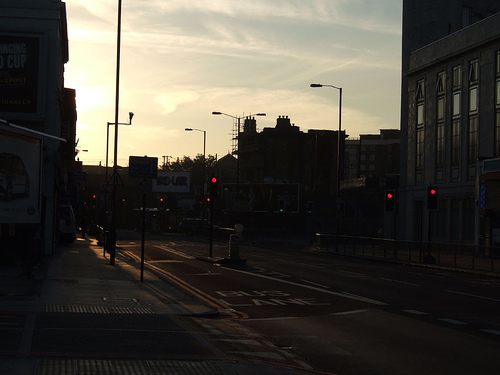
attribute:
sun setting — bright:
[68, 53, 109, 120]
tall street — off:
[100, 105, 407, 345]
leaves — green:
[176, 133, 221, 191]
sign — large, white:
[155, 168, 193, 195]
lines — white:
[139, 242, 499, 340]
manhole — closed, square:
[81, 279, 169, 317]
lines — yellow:
[131, 224, 269, 340]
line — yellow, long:
[162, 267, 217, 308]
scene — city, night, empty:
[6, 21, 417, 355]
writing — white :
[214, 288, 329, 312]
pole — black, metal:
[110, 0, 122, 266]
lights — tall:
[180, 82, 350, 139]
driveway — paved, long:
[0, 299, 310, 365]